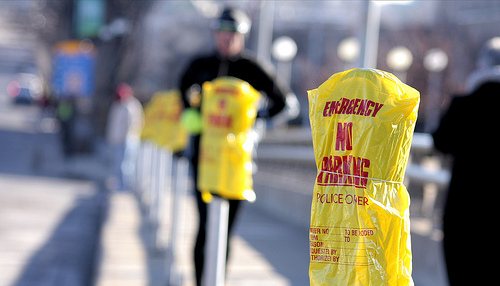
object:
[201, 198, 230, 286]
metal pole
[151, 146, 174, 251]
pole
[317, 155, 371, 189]
words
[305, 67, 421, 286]
bag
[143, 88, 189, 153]
bag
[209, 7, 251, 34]
hat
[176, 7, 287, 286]
woman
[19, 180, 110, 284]
shadow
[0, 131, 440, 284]
ground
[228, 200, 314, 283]
shadow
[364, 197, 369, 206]
writing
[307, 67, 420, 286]
cover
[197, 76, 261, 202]
cover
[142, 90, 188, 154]
cover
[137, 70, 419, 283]
meters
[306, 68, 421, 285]
plastic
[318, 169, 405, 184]
string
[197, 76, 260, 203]
yellow plastic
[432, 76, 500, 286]
black coat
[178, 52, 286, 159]
black coat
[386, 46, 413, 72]
street light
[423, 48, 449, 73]
street light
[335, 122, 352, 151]
no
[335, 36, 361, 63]
lights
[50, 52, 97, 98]
blue sign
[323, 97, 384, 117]
word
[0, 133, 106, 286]
road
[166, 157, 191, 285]
pole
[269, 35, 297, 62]
light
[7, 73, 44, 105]
car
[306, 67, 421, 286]
parking meter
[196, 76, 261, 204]
parking meter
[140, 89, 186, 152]
parking meter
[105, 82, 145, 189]
man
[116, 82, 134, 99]
cap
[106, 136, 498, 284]
sidewalk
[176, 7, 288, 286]
man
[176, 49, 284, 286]
uniform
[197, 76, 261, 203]
bag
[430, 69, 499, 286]
man